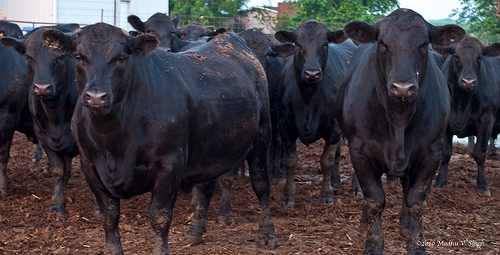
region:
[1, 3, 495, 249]
Cows facing the picture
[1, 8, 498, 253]
Cows are brown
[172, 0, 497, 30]
Trees behind the cows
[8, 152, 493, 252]
Wooden chips on the soil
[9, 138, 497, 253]
Wooden chips under cows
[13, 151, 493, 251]
Cows step on wooden chips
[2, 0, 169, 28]
Building next to the pen of cows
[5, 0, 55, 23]
Building has a white door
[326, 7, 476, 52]
Ears of cow are extended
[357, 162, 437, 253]
Front legs of cow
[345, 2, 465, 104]
the head of a black cow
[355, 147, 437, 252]
the legs of a black cow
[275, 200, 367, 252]
brown mud on the ground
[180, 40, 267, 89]
mud on the back of a cow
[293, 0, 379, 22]
green leaves on a tree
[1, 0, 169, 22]
the wall of a building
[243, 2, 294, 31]
buildings in the background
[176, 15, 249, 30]
wire mesh in the backgroung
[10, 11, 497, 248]
many black cows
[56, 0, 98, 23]
a blue painted wall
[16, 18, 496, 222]
All the animals in this picture are black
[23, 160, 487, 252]
Animals are standing in dirt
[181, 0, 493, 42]
Trees are in the background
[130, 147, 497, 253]
Animals legs are dirty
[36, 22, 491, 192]
Animals have the appearance of a cow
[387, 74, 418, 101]
Animals nose is brown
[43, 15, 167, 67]
Animals ears are round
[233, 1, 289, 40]
House is in the far background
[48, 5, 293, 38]
Wired fence is in the background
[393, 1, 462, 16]
Sky is bright and powder blue in color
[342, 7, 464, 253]
Big black cow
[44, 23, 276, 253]
Large dirty black cow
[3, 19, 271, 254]
Two very large black cows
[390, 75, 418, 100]
cows nose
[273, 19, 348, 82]
face of a black cow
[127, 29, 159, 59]
Left ear of a black cow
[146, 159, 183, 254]
left front leg of a black cow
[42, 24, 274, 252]
Large black female cow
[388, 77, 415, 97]
cow nose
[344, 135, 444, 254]
legs of a black cow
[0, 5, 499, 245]
Herd of cows in a cowshed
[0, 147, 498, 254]
Wood chips on soil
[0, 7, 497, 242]
Cows are facing forward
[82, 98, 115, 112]
Muzzle of cow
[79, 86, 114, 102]
Nostril of cow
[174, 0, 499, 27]
Trees in the background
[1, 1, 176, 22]
Building next to cowshed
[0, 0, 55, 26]
White door of building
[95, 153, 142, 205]
Brisket of cow is black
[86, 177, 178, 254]
Front legs of cow